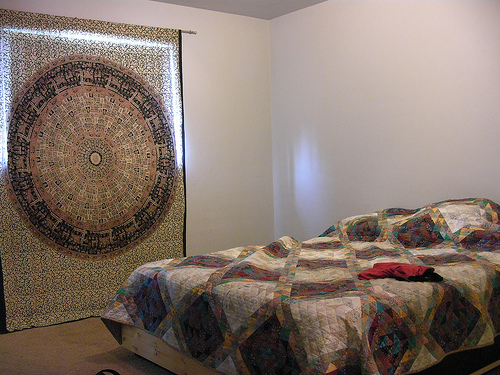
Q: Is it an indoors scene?
A: Yes, it is indoors.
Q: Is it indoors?
A: Yes, it is indoors.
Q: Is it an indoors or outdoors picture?
A: It is indoors.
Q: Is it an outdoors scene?
A: No, it is indoors.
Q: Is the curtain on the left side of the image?
A: Yes, the curtain is on the left of the image.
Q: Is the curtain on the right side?
A: No, the curtain is on the left of the image.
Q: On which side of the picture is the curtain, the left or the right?
A: The curtain is on the left of the image.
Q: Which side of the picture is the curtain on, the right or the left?
A: The curtain is on the left of the image.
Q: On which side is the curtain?
A: The curtain is on the left of the image.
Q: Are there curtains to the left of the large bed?
A: Yes, there is a curtain to the left of the bed.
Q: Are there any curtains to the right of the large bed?
A: No, the curtain is to the left of the bed.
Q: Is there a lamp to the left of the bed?
A: No, there is a curtain to the left of the bed.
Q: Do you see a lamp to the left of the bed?
A: No, there is a curtain to the left of the bed.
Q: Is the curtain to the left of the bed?
A: Yes, the curtain is to the left of the bed.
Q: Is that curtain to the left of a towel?
A: No, the curtain is to the left of the bed.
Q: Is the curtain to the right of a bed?
A: No, the curtain is to the left of a bed.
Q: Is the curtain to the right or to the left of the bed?
A: The curtain is to the left of the bed.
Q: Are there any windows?
A: Yes, there is a window.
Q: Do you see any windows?
A: Yes, there is a window.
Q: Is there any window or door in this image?
A: Yes, there is a window.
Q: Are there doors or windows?
A: Yes, there is a window.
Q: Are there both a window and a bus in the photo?
A: No, there is a window but no buses.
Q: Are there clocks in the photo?
A: No, there are no clocks.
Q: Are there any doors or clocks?
A: No, there are no clocks or doors.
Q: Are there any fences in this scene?
A: No, there are no fences.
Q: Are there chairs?
A: No, there are no chairs.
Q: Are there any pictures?
A: No, there are no pictures.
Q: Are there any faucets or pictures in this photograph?
A: No, there are no pictures or faucets.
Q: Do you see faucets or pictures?
A: No, there are no pictures or faucets.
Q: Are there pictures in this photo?
A: No, there are no pictures.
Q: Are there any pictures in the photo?
A: No, there are no pictures.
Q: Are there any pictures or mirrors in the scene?
A: No, there are no pictures or mirrors.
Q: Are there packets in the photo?
A: No, there are no packets.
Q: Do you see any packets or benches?
A: No, there are no packets or benches.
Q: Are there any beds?
A: Yes, there is a bed.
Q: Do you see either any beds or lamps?
A: Yes, there is a bed.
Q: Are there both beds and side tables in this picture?
A: No, there is a bed but no side tables.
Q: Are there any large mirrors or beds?
A: Yes, there is a large bed.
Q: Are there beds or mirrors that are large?
A: Yes, the bed is large.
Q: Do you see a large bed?
A: Yes, there is a large bed.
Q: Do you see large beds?
A: Yes, there is a large bed.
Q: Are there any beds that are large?
A: Yes, there is a bed that is large.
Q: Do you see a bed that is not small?
A: Yes, there is a large bed.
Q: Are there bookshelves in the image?
A: No, there are no bookshelves.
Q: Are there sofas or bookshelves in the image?
A: No, there are no bookshelves or sofas.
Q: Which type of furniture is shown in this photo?
A: The furniture is a bed.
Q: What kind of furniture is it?
A: The piece of furniture is a bed.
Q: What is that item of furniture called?
A: That is a bed.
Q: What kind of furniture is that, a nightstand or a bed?
A: That is a bed.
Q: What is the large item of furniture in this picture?
A: The piece of furniture is a bed.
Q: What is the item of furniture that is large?
A: The piece of furniture is a bed.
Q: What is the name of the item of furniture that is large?
A: The piece of furniture is a bed.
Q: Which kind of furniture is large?
A: The furniture is a bed.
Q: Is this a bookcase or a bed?
A: This is a bed.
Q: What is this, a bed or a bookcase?
A: This is a bed.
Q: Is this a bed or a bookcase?
A: This is a bed.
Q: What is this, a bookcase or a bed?
A: This is a bed.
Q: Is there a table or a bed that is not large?
A: No, there is a bed but it is large.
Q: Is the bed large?
A: Yes, the bed is large.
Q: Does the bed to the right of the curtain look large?
A: Yes, the bed is large.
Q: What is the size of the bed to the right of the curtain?
A: The bed is large.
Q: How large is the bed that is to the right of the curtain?
A: The bed is large.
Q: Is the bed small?
A: No, the bed is large.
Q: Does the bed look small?
A: No, the bed is large.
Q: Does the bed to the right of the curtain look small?
A: No, the bed is large.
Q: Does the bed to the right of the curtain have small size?
A: No, the bed is large.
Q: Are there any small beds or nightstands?
A: No, there is a bed but it is large.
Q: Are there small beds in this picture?
A: No, there is a bed but it is large.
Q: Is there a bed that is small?
A: No, there is a bed but it is large.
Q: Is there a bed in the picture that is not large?
A: No, there is a bed but it is large.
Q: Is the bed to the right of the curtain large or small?
A: The bed is large.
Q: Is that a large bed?
A: Yes, that is a large bed.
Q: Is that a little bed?
A: No, that is a large bed.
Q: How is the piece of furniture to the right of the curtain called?
A: The piece of furniture is a bed.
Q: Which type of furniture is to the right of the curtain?
A: The piece of furniture is a bed.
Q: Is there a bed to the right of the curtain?
A: Yes, there is a bed to the right of the curtain.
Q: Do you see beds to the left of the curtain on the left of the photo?
A: No, the bed is to the right of the curtain.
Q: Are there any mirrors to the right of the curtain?
A: No, there is a bed to the right of the curtain.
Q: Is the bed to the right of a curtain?
A: Yes, the bed is to the right of a curtain.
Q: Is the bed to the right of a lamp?
A: No, the bed is to the right of a curtain.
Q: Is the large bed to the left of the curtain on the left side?
A: No, the bed is to the right of the curtain.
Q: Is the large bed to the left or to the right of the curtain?
A: The bed is to the right of the curtain.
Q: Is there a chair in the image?
A: No, there are no chairs.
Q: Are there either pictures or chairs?
A: No, there are no chairs or pictures.